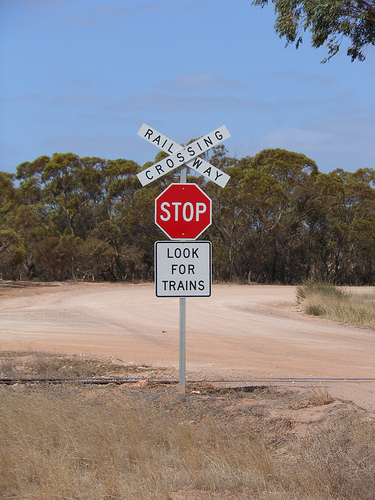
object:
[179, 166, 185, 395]
pole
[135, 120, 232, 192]
traffic sign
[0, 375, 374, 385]
line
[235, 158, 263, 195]
dark green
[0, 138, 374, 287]
tree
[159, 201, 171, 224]
letter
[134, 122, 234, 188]
sign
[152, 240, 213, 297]
sign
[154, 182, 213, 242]
stop sign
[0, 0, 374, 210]
sky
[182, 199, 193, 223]
letter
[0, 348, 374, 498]
brown grass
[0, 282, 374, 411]
road